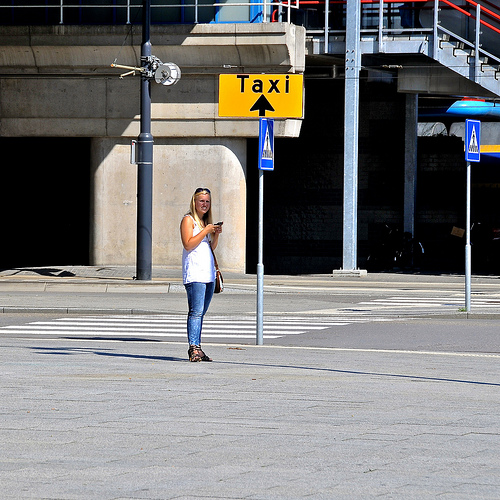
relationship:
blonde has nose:
[179, 187, 224, 365] [200, 202, 205, 209]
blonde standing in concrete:
[179, 187, 224, 365] [0, 341, 499, 498]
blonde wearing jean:
[179, 187, 224, 365] [184, 282, 208, 356]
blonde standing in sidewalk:
[179, 187, 224, 365] [3, 336, 497, 497]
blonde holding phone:
[179, 187, 224, 365] [211, 217, 226, 236]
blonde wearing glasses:
[179, 179, 229, 369] [195, 186, 215, 198]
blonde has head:
[179, 179, 229, 369] [180, 181, 221, 228]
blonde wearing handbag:
[179, 187, 224, 365] [208, 239, 225, 296]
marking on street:
[258, 269, 464, 351] [2, 273, 497, 498]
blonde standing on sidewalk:
[179, 187, 224, 365] [0, 283, 332, 314]